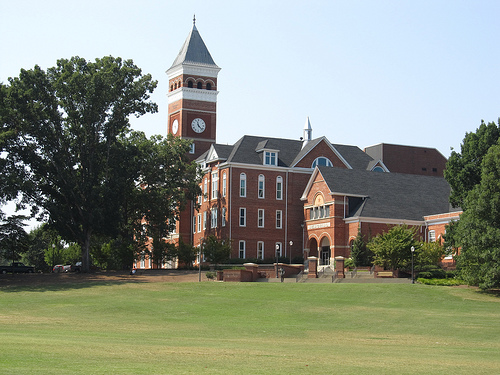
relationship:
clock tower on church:
[161, 7, 233, 163] [139, 146, 459, 273]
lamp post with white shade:
[404, 241, 423, 286] [408, 239, 418, 253]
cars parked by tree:
[0, 261, 84, 275] [1, 54, 159, 272]